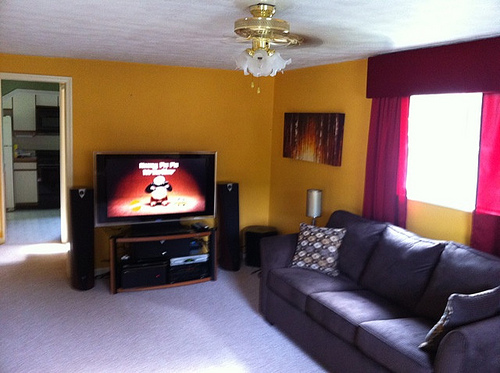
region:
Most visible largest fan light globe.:
[246, 47, 273, 77]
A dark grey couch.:
[257, 209, 497, 371]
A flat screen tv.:
[92, 152, 214, 227]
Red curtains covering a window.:
[362, 34, 498, 260]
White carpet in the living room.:
[0, 242, 327, 372]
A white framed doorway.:
[0, 71, 73, 242]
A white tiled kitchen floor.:
[3, 206, 61, 246]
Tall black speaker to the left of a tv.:
[62, 185, 97, 290]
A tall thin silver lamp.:
[306, 187, 322, 226]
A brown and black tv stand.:
[105, 224, 220, 294]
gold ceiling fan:
[166, 3, 391, 94]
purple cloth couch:
[258, 208, 499, 371]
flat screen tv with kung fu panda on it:
[94, 149, 213, 222]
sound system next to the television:
[70, 179, 242, 289]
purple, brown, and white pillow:
[292, 220, 344, 278]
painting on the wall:
[281, 110, 343, 168]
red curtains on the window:
[365, 35, 499, 259]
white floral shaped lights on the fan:
[233, 50, 292, 79]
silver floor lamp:
[306, 186, 323, 226]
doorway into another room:
[0, 73, 75, 243]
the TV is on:
[97, 154, 216, 220]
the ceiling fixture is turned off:
[234, 0, 294, 94]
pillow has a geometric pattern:
[293, 221, 345, 276]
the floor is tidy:
[1, 244, 321, 371]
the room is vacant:
[4, 3, 498, 369]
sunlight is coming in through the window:
[403, 92, 482, 212]